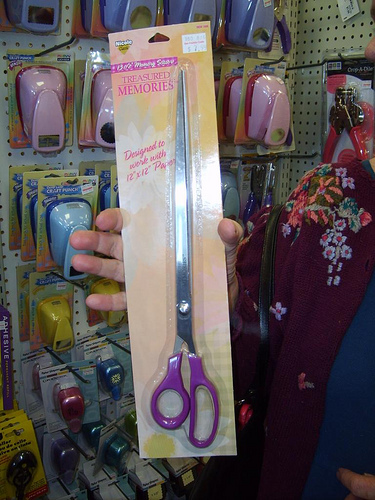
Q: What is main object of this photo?
A: Scissors.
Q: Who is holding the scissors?
A: A woman.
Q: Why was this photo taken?
A: To show scissors.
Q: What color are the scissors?
A: Purple and silver.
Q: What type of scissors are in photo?
A: Long and metal.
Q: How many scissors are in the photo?
A: One.